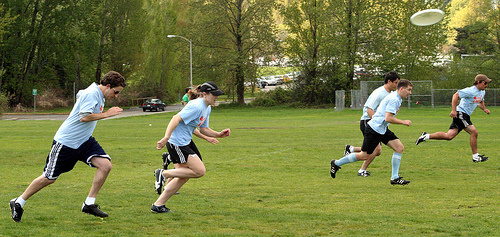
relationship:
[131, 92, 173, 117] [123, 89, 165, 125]
car on street